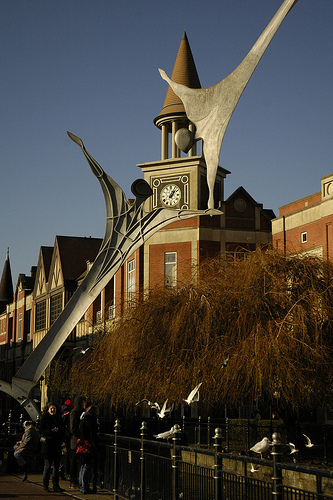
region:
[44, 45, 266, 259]
statues of dancers above the people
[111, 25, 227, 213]
a clock tower above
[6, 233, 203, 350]
buildings in the area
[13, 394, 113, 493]
these people are looking at something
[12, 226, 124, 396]
a long part of a statue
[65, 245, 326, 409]
a big tree in the area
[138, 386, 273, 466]
birds on the fence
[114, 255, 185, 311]
windows on the building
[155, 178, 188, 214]
a clock on the building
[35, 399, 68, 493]
this girl is watching the photographer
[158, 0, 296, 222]
a large gray statue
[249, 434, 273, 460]
a large white bird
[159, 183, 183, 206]
a building wall clock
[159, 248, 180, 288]
a window of a building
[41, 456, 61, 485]
a woman's blue jean pants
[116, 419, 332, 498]
part of a black iron gate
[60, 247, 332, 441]
a large brown tree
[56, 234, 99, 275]
part of a building's roof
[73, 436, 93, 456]
a red and black bag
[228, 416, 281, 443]
a large green bush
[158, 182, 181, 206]
clock on the building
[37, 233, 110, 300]
roof on the building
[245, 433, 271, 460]
bird on the fence post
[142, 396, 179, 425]
bird flying in the air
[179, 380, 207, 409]
bird flying in the air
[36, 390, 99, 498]
people by the fence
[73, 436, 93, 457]
woman holding a red bag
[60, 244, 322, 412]
tree in front of the building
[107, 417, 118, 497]
post on the black fence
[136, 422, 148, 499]
post on the black fence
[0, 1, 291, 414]
Metal statues of people in the forefront.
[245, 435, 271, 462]
Bird on the fence.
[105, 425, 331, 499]
Black metal fence beside the sidewalk.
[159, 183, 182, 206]
Clock on the side of the building.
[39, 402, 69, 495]
Woman walking on the sidewalk.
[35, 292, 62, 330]
Windows on the side of the building.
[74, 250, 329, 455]
Tree in the fenced area.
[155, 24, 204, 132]
Cone cylinder on top of the building.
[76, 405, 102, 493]
Woman carrying red purse.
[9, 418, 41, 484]
Woman sitting on bench.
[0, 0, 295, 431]
Metal art sculpture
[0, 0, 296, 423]
Art sculpture of two people holding hands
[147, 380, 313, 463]
White seagulls near an iron fence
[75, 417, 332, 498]
Iron fence lining a sidewalk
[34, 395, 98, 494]
Four people standing on a sidewalk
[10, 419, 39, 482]
Woman sitting on the base of a sculpture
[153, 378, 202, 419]
Two white seagulls flying in the air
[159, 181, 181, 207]
White analog clock on a building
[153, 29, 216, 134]
Light brown cone tower roof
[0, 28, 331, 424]
Large brown brick building